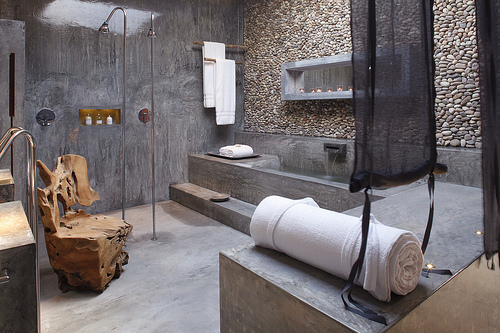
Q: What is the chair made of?
A: Wood.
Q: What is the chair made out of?
A: It's wood.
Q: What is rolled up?
A: A mat.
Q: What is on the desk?
A: A rolled up towel.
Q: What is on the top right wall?
A: It's stones.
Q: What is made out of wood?
A: A chair.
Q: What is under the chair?
A: The floor.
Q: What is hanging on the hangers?
A: It's towels.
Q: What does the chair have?
A: It has holes.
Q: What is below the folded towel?
A: It's a counter.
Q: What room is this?
A: Bathroom.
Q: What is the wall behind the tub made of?
A: Small, round rocks.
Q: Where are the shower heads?
A: On two tall poles.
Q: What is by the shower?
A: A chair.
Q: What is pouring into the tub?
A: Water.